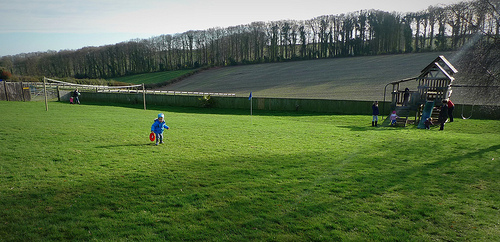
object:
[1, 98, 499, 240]
grass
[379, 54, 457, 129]
playground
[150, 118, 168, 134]
jacket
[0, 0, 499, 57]
sky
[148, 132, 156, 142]
frisbee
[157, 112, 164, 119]
hat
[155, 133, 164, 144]
pants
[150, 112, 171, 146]
children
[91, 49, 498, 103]
large hill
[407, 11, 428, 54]
trees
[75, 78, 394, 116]
fence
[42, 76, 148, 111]
volleyball net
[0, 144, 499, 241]
shadow